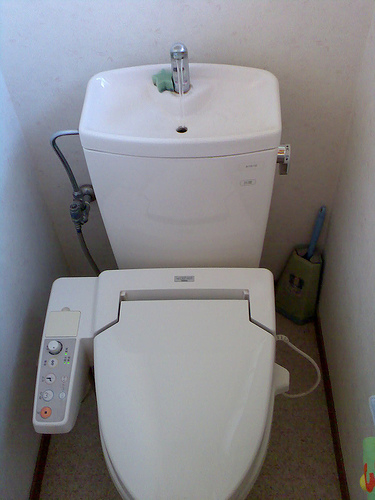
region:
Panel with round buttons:
[29, 332, 86, 437]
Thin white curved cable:
[273, 327, 325, 406]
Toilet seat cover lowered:
[86, 295, 277, 497]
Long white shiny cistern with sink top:
[75, 41, 291, 269]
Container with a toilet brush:
[270, 199, 330, 320]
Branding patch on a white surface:
[170, 271, 194, 282]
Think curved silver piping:
[47, 123, 98, 273]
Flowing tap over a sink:
[78, 37, 279, 142]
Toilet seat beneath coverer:
[88, 266, 291, 499]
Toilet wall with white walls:
[1, 1, 373, 499]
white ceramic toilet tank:
[79, 59, 283, 267]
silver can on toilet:
[170, 44, 190, 94]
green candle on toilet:
[152, 66, 174, 93]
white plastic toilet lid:
[92, 298, 276, 499]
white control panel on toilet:
[32, 275, 97, 438]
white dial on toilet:
[48, 340, 61, 355]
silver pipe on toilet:
[48, 128, 87, 191]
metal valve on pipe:
[65, 185, 95, 227]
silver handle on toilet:
[278, 142, 289, 180]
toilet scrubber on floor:
[277, 206, 325, 328]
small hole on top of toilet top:
[166, 122, 191, 135]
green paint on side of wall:
[353, 434, 370, 485]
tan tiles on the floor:
[287, 453, 314, 484]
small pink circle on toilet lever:
[33, 404, 57, 421]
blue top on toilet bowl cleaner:
[299, 195, 327, 251]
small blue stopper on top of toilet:
[141, 65, 185, 91]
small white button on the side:
[43, 339, 67, 352]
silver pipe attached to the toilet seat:
[28, 126, 91, 231]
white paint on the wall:
[301, 60, 341, 105]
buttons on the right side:
[38, 329, 63, 425]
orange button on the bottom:
[40, 403, 59, 431]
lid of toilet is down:
[123, 310, 244, 499]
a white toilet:
[95, 279, 253, 499]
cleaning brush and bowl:
[282, 204, 317, 324]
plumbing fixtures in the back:
[50, 127, 91, 276]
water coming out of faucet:
[174, 60, 194, 130]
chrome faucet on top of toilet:
[165, 45, 200, 94]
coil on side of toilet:
[285, 327, 315, 411]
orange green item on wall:
[360, 442, 373, 498]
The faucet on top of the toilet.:
[170, 48, 190, 89]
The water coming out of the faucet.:
[174, 60, 185, 131]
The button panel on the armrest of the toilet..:
[37, 338, 70, 424]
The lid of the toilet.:
[95, 296, 263, 499]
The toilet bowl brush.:
[272, 196, 321, 322]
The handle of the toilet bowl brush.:
[308, 203, 325, 260]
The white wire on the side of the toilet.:
[279, 335, 322, 401]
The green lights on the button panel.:
[60, 347, 73, 370]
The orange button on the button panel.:
[40, 407, 51, 416]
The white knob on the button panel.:
[46, 339, 61, 352]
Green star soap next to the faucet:
[150, 68, 177, 92]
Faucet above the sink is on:
[167, 42, 191, 92]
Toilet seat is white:
[94, 267, 277, 498]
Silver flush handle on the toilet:
[274, 143, 290, 175]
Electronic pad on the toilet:
[30, 276, 98, 434]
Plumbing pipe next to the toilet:
[48, 129, 103, 277]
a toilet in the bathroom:
[35, 274, 270, 488]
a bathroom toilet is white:
[43, 278, 294, 490]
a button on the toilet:
[41, 403, 55, 420]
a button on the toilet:
[43, 384, 54, 399]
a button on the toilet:
[41, 372, 57, 384]